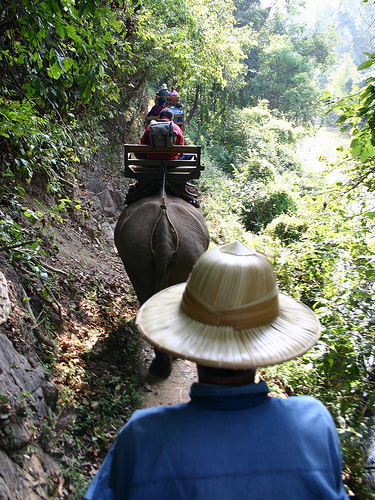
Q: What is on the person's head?
A: A hat.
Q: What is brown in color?
A: The hat.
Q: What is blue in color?
A: The t-shirt.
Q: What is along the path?
A: Some trees.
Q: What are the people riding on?
A: Elephants.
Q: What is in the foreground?
A: A person.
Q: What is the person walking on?
A: A path.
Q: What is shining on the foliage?
A: The sun.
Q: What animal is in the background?
A: An elephant.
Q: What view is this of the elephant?
A: A back view.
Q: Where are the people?
A: On the elephant.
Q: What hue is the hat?
A: Tan.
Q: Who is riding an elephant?
A: The man.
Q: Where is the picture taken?
A: In the forest.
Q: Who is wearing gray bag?
A: Man in red.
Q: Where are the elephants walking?
A: Dirt road.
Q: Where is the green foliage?
A: Along the path.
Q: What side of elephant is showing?
A: Back end.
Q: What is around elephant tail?
A: Rope.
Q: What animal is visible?
A: Elephant.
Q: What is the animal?
A: A elephant.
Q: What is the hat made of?
A: Straw.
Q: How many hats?
A: Two.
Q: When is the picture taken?
A: Daytime.